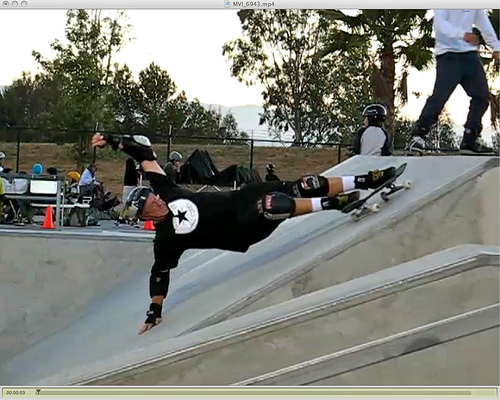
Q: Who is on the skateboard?
A: Elderly man.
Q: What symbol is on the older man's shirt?
A: Star.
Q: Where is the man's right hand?
A: Ramp.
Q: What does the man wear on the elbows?
A: Elbow pads.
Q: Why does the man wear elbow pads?
A: Safety.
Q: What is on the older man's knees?
A: Knee Pads.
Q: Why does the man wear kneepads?
A: Safety.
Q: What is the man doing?
A: Skating.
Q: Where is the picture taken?
A: A skatepark.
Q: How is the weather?
A: Clear.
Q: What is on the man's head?
A: Helmet.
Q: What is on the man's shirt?
A: A star.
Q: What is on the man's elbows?
A: Pads.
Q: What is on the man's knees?
A: Pads.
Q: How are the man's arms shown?
A: Extended.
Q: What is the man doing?
A: Falling.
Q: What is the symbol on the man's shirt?
A: Star.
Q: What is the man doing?
A: Skateboarding.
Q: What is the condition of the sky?
A: Cloudy.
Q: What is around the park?
A: Fence.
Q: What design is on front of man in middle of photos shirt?
A: Star.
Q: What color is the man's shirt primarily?
A: Black.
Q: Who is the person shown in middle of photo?
A: Skateboarder.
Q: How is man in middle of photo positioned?
A: Sideways.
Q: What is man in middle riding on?
A: Skateboard.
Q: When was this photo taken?
A: Daytime.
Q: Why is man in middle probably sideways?
A: Doing stunt.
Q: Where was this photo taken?
A: Skateboard ramp.